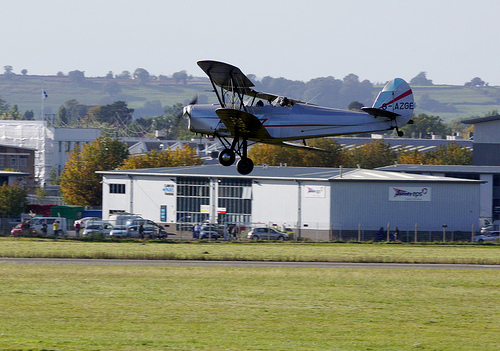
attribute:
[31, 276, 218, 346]
grass — green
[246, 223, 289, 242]
car — small, grey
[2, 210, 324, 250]
lot — parking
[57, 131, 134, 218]
tree — large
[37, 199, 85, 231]
container — green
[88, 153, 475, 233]
building — white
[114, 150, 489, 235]
building — grey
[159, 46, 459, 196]
plane — silver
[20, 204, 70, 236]
van — white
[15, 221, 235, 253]
parking lot — full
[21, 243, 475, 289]
runway — paved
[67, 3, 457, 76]
sky — bright grey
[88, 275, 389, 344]
grass — green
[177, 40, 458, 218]
plane — grey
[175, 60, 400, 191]
plane — red, striped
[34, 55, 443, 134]
hill — rising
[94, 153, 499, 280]
building — white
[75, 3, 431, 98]
clouds — grey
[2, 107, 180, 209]
building — white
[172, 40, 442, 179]
plane — flying, low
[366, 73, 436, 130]
stablizer — vertical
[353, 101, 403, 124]
stablizer — horizontal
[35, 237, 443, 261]
grass — green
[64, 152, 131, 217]
trees — green